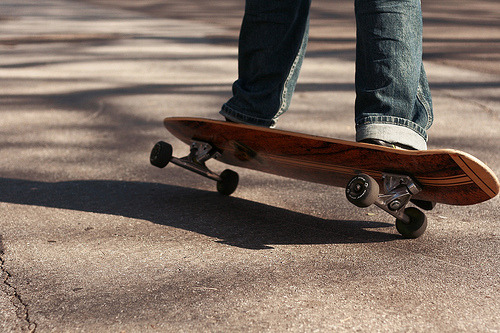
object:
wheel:
[150, 140, 174, 168]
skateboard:
[149, 116, 500, 239]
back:
[247, 144, 329, 166]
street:
[3, 5, 491, 332]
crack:
[1, 253, 34, 332]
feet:
[364, 138, 408, 150]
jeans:
[217, 0, 434, 151]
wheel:
[215, 168, 241, 199]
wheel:
[344, 173, 379, 208]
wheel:
[394, 206, 429, 240]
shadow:
[0, 177, 402, 251]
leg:
[353, 0, 435, 152]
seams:
[353, 114, 428, 141]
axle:
[170, 138, 219, 182]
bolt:
[353, 183, 363, 190]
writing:
[356, 177, 370, 184]